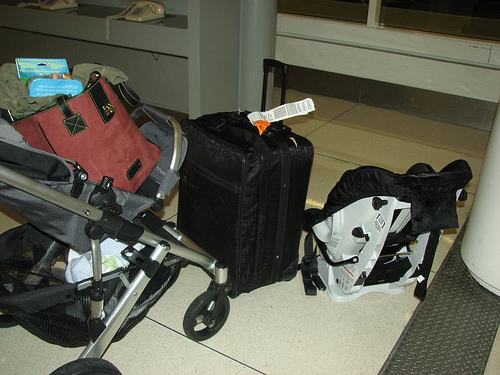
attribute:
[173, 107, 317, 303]
luggage — black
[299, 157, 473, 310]
car seat — black, white, grey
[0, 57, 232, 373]
baby stroller — grey, in picture, cluttered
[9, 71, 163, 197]
bag — maroon, red, black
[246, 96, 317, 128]
luggage sticker — white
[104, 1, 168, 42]
corded telephone — beige, old-style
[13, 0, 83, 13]
corded telephone — beige, old-style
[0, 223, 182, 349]
basket — black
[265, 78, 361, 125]
floor tile — white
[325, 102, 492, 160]
floor tile — white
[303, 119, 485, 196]
floor tile — white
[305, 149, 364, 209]
floor tile — white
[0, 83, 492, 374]
floor — brown, white, in picture, tan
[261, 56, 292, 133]
handle — black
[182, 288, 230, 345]
wheel — black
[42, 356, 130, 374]
wheel — black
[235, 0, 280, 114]
pole — white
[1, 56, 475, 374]
area — cluttered